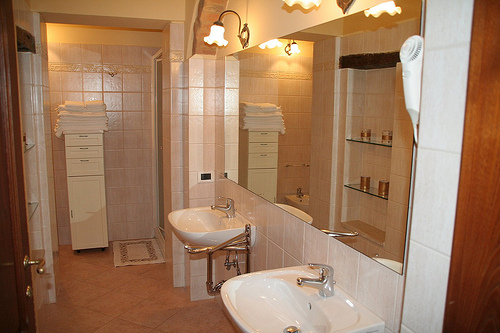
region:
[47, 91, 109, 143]
stack of fresh white towels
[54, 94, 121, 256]
pile of towels on cabinet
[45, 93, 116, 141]
stack of towels next to shower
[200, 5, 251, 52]
flower shaped light fixture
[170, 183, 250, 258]
white porcelain sink with silver faucet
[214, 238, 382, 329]
white porcelain sink with silver faucet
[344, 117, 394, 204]
bottles reflected in mirror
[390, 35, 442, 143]
white air freshener on wall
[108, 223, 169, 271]
shower rug on flower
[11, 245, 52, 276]
silver lever door knob on brown door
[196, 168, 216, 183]
Electrical outlet next to white sink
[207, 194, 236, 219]
Silver faucet above white sink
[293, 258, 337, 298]
Silver faucet above white sink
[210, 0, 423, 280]
Mirror above white sink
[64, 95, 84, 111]
White towel is folded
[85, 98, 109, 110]
White towel is folded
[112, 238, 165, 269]
Small white rug next to dresser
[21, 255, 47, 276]
Gold handle on door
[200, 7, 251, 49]
Light fixture is lit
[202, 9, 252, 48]
Light fixture above mirror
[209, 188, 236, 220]
the facet in the sink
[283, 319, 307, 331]
the drain in the bottom of the sink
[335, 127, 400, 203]
the glass shelfs on the wall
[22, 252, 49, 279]
the door handle on the open door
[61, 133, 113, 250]
the white cabinet agianst the wall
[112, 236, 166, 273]
the rug at the base of the shower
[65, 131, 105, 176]
the drawers on the white cabinet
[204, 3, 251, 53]
the light abover the mirror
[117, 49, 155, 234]
the tile wall in the bathroom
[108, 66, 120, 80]
the hook on the tile wall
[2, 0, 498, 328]
Bathroom with Two Sinks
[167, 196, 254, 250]
Sink Basin with Faucett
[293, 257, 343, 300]
Stainless Steel Bathroom Faucett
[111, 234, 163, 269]
Beige and Tan Bathroom Rug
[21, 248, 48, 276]
Stainless Steel Bathroom Door Knob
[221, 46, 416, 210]
Large Bathroom Mirror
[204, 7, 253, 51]
Tulip Glass Bathroom Fixture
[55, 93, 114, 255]
Eggshell Colored Bathroom Cabinet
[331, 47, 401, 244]
Mirror Reflection of Bathroom Glass Shelves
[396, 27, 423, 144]
Mounted Blow Dryer in Bathroom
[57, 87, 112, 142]
a stack of towels on a cabinet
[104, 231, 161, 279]
a rug on the floor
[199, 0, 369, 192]
a large mirror on the wall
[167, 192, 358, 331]
two bathroom sinks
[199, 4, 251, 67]
a light mounted to the wall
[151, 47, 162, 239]
a shower door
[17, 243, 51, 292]
a brass door handle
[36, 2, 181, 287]
a open walk way to the next room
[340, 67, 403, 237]
glass shelves on the wall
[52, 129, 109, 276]
a white cabinet with drawers